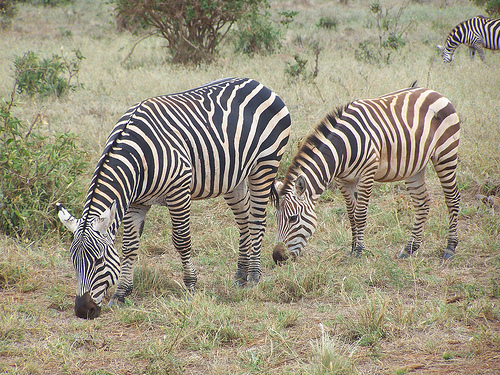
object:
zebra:
[271, 87, 463, 265]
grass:
[0, 0, 499, 374]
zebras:
[59, 77, 461, 316]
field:
[0, 0, 499, 374]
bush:
[278, 53, 304, 81]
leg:
[357, 190, 370, 252]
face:
[68, 222, 116, 314]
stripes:
[168, 98, 207, 194]